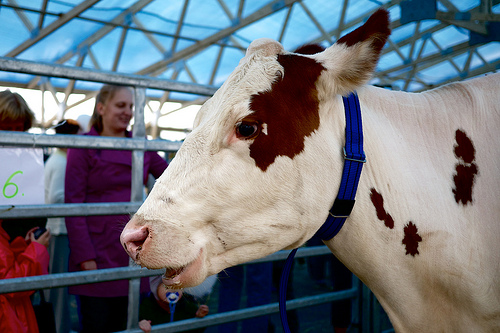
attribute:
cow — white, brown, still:
[117, 8, 499, 332]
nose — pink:
[119, 220, 150, 264]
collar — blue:
[306, 90, 366, 251]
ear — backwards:
[325, 8, 390, 94]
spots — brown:
[452, 128, 480, 206]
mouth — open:
[147, 237, 206, 290]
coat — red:
[0, 220, 50, 332]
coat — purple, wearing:
[65, 124, 168, 296]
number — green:
[3, 169, 24, 198]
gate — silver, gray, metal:
[0, 56, 391, 331]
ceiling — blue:
[0, 0, 499, 100]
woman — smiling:
[64, 83, 169, 331]